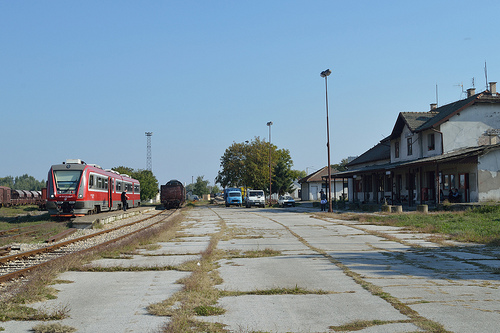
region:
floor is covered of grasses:
[154, 219, 220, 330]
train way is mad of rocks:
[56, 231, 118, 268]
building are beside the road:
[317, 130, 477, 196]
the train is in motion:
[161, 167, 191, 210]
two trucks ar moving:
[218, 169, 285, 210]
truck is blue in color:
[212, 172, 254, 221]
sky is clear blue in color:
[146, 61, 203, 113]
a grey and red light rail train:
[40, 164, 142, 215]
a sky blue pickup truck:
[224, 188, 246, 206]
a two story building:
[337, 91, 499, 226]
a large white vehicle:
[246, 188, 267, 208]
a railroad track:
[1, 202, 186, 288]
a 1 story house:
[302, 160, 358, 201]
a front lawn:
[365, 206, 498, 261]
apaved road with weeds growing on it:
[0, 212, 499, 332]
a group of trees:
[216, 138, 307, 203]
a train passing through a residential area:
[21, 46, 489, 289]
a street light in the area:
[311, 66, 341, 218]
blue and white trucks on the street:
[224, 181, 272, 209]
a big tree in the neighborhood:
[215, 135, 295, 187]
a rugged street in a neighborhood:
[173, 212, 443, 323]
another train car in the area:
[156, 168, 191, 208]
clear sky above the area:
[28, 27, 298, 117]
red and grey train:
[45, 155, 142, 217]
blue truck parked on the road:
[214, 183, 241, 205]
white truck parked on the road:
[246, 179, 266, 209]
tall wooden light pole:
[316, 64, 344, 209]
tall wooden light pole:
[263, 114, 278, 204]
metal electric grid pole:
[144, 127, 154, 204]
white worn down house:
[342, 77, 498, 209]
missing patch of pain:
[474, 168, 499, 197]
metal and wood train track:
[0, 208, 177, 301]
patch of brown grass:
[149, 221, 229, 331]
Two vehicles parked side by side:
[221, 184, 271, 210]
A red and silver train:
[38, 158, 146, 217]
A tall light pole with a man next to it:
[318, 60, 336, 210]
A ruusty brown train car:
[153, 178, 188, 209]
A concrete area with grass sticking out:
[161, 232, 231, 332]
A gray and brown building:
[383, 113, 483, 205]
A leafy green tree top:
[233, 138, 282, 186]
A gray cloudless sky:
[158, 45, 258, 100]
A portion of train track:
[8, 236, 104, 266]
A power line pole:
[140, 131, 161, 170]